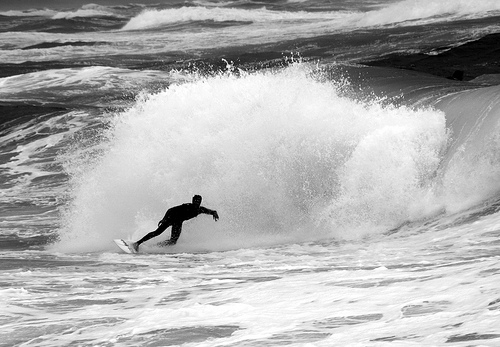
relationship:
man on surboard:
[150, 178, 215, 246] [119, 233, 137, 260]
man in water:
[150, 178, 215, 246] [60, 53, 99, 81]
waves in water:
[185, 77, 366, 176] [60, 53, 99, 81]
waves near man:
[185, 77, 366, 176] [150, 178, 215, 246]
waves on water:
[185, 77, 366, 176] [60, 53, 99, 81]